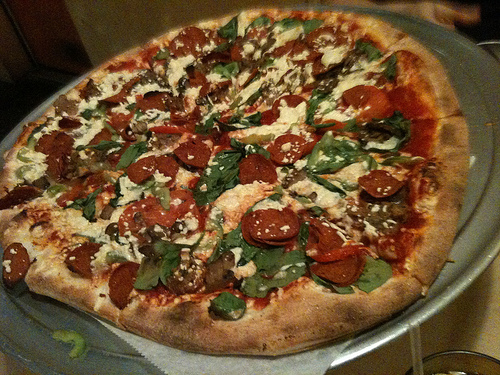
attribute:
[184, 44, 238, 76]
pizza — cheesy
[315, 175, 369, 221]
toppings — cooked, cheesy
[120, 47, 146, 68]
crust — golden